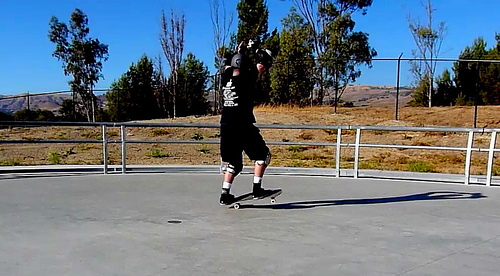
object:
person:
[219, 36, 274, 203]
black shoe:
[252, 183, 271, 199]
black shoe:
[220, 188, 235, 205]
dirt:
[0, 106, 500, 175]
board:
[227, 193, 282, 210]